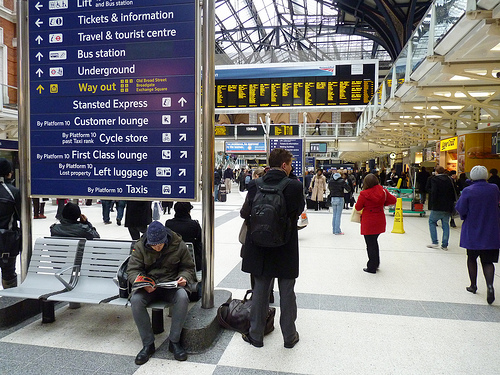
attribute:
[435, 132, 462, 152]
sign — yellow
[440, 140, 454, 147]
writing — black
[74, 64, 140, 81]
text — white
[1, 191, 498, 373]
tile flooring — white, grey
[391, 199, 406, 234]
pylon — is yellow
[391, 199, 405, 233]
sign — yellow, wet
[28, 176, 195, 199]
sign — blue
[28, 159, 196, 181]
sign — blue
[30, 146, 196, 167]
sign — blue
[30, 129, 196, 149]
sign — blue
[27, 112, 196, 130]
sign — blue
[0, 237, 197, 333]
bench — metal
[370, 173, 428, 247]
cone — yellow, caution cone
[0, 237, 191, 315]
seats — grey, plastic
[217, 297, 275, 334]
bag — black, leather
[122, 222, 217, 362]
man — writing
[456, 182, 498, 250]
coat — blue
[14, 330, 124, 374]
ground — tiled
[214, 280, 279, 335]
duffle bag — is black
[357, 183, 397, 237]
coat — red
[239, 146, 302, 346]
man — young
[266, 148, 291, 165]
hair — short, brown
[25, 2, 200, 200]
sign — blue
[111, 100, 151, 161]
writing — white